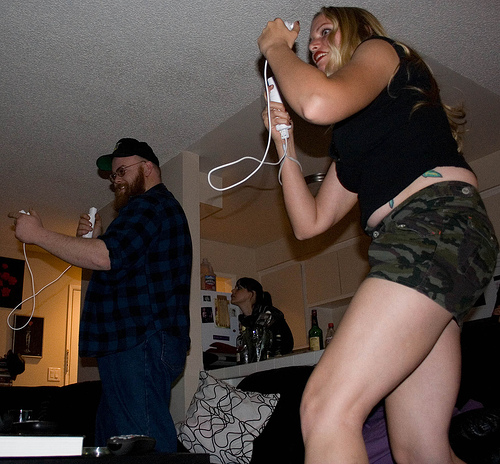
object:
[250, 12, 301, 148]
controllers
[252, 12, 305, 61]
hands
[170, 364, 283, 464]
pillow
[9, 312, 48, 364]
picture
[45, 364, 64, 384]
switch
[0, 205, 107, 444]
wall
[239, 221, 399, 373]
kitchen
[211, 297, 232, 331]
refrigerator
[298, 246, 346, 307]
cabinets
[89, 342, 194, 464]
jeans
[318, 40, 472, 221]
shirt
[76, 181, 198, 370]
shirt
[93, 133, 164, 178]
cap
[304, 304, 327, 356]
bottle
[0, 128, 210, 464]
man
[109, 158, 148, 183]
eyeglasses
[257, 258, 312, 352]
drawer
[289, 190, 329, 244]
elbow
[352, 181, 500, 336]
shorts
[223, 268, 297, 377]
people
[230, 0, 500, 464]
girl